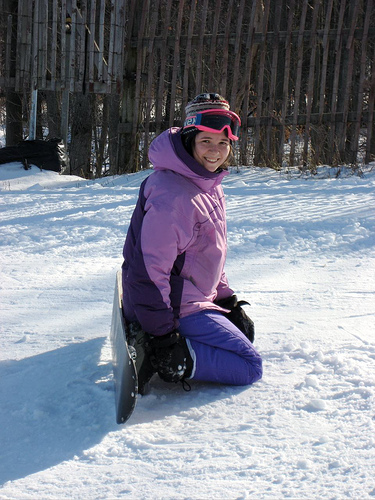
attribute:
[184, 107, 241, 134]
goggles — pink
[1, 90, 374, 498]
snow — white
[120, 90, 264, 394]
women — smiling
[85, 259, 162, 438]
snowboard — long, black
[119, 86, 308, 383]
girl — young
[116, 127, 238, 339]
jacket — long-sleeved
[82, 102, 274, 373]
girl — smiling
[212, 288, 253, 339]
glove — brown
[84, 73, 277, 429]
girl — young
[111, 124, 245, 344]
jacket — lavender, purple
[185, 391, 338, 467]
snow — white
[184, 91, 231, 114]
cap — wool 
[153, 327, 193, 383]
glove — black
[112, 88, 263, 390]
girl — young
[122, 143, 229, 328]
coat — purple, pink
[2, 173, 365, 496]
snow — white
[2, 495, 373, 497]
snow — white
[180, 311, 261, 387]
pants — blue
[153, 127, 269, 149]
eyewear — pink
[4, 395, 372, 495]
snow — white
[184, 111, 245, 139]
goggles — pink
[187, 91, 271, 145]
goggles — black, pink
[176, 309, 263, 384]
pants — lavender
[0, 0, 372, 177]
fence — old, weathered, wooden